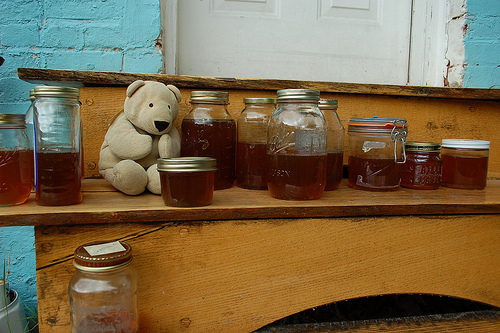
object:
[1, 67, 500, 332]
wood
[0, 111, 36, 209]
jar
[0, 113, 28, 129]
lid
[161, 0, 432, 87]
door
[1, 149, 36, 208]
something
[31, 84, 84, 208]
jar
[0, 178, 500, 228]
shelf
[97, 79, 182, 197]
bear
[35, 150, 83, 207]
honey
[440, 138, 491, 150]
lid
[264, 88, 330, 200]
jar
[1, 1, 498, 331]
wall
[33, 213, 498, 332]
step bottom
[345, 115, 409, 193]
jar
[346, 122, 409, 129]
rubber seal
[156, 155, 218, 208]
jar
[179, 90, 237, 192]
jar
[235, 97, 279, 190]
jar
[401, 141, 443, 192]
jar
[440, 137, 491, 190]
jar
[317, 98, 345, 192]
jar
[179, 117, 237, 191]
honey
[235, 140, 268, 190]
honey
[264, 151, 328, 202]
honey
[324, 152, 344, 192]
honey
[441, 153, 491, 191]
honey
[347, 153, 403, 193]
honey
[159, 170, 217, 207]
honey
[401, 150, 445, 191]
honey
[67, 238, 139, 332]
jar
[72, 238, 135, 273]
lid